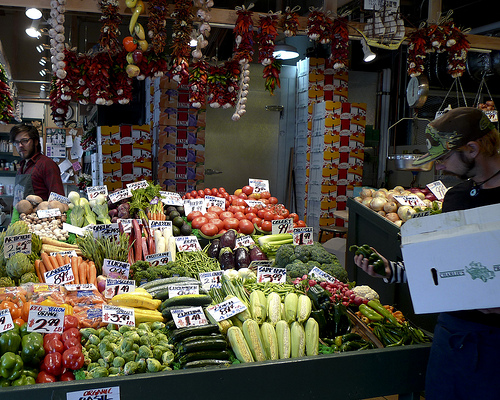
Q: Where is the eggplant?
A: In between the celery and green beans.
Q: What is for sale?
A: Produce.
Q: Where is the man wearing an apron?
A: Behind the produce table.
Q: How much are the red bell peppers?
A: $2.99 lb.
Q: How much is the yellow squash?
A: $1.49 lb.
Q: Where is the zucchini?
A: In between the corn and brussel sprouts.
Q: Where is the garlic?
A: Hanging above.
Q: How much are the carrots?
A: $0.89 lb.